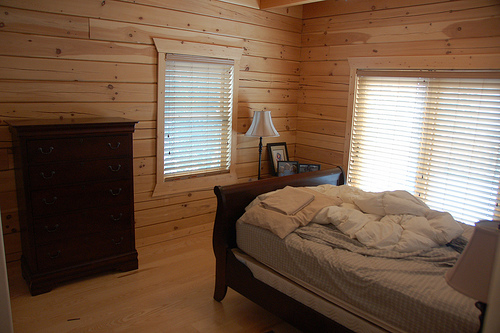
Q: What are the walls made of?
A: Wood.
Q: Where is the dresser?
A: On the wall.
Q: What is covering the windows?
A: Shades.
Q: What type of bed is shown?
A: Sleigh.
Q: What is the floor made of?
A: Hard wood.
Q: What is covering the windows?
A: Blinds.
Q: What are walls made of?
A: Wood.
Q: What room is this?
A: Bedroom.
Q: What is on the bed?
A: Comforter.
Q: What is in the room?
A: Bed.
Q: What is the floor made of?
A: Wood.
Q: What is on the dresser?
A: A lamp and picture.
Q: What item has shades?
A: The window.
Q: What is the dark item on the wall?
A: The dresser.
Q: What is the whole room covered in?
A: Wood.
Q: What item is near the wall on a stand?
A: The lamp.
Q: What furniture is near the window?
A: The bed.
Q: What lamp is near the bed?
A: The lamp on the right.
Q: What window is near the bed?
A: The biggest one.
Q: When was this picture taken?
A: Daytime.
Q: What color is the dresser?
A: Brown.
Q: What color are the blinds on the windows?
A: White.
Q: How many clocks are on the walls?
A: Zero.